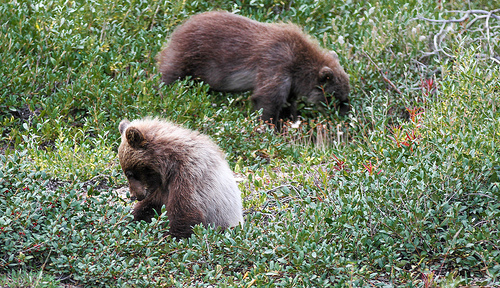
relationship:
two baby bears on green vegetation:
[115, 10, 352, 233] [0, 1, 499, 286]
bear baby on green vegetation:
[112, 116, 246, 236] [0, 1, 499, 286]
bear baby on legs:
[112, 116, 246, 236] [124, 198, 204, 244]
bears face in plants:
[307, 57, 352, 125] [295, 109, 371, 155]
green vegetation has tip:
[0, 1, 499, 286] [364, 157, 378, 174]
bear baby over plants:
[112, 116, 246, 236] [80, 103, 268, 263]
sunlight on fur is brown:
[167, 114, 236, 203] [157, 11, 346, 121]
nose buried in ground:
[315, 110, 353, 127] [235, 117, 465, 210]